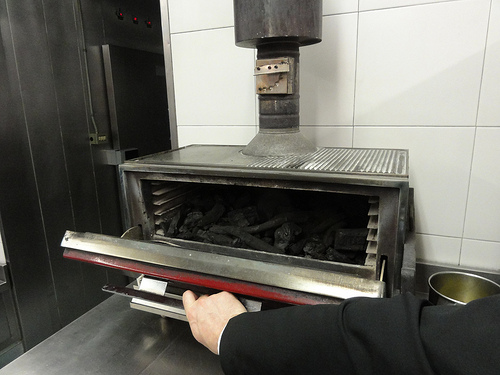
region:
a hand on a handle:
[133, 289, 244, 349]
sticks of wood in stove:
[173, 212, 353, 263]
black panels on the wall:
[10, 6, 100, 217]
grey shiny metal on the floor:
[36, 311, 199, 373]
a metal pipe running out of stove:
[199, 52, 366, 160]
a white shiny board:
[319, 32, 477, 133]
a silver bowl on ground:
[401, 260, 498, 310]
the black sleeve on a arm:
[191, 287, 496, 372]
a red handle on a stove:
[45, 241, 222, 282]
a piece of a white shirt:
[203, 319, 234, 357]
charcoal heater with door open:
[52, 117, 437, 366]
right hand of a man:
[175, 280, 259, 365]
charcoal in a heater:
[186, 211, 323, 245]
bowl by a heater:
[428, 262, 494, 308]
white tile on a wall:
[418, 58, 488, 243]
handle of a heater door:
[97, 277, 195, 329]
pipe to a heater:
[219, 3, 361, 132]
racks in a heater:
[347, 197, 377, 279]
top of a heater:
[329, 145, 401, 175]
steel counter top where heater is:
[41, 339, 193, 369]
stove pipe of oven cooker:
[222, 2, 333, 166]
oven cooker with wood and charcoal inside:
[50, 134, 424, 349]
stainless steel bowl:
[419, 261, 499, 318]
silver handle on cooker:
[94, 265, 265, 341]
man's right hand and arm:
[172, 283, 498, 373]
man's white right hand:
[175, 283, 253, 358]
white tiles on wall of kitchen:
[160, 2, 497, 268]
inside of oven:
[120, 168, 388, 286]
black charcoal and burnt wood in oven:
[155, 193, 363, 268]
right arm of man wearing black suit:
[210, 290, 499, 371]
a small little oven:
[95, 142, 415, 319]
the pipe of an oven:
[238, 40, 318, 154]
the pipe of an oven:
[214, 0, 331, 60]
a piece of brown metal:
[250, 55, 292, 100]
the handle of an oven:
[105, 274, 182, 325]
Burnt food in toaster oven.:
[181, 199, 361, 240]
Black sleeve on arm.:
[231, 305, 496, 365]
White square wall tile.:
[358, 17, 481, 131]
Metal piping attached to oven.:
[256, 55, 303, 155]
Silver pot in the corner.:
[426, 270, 499, 299]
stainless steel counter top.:
[62, 325, 127, 368]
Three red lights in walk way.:
[111, 8, 159, 27]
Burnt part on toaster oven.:
[68, 229, 88, 241]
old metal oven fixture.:
[255, 59, 297, 96]